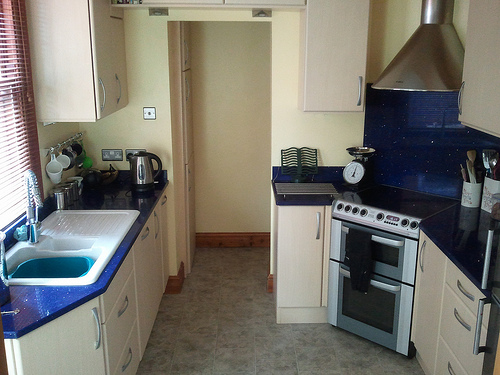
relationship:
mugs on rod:
[436, 179, 490, 224] [29, 123, 121, 180]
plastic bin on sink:
[7, 254, 94, 278] [2, 205, 144, 292]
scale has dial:
[337, 140, 379, 193] [342, 141, 379, 161]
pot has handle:
[128, 152, 169, 195] [142, 150, 165, 182]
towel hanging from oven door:
[346, 222, 373, 297] [333, 220, 409, 283]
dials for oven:
[335, 202, 418, 237] [334, 210, 396, 342]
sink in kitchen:
[2, 205, 144, 292] [3, 2, 484, 362]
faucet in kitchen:
[21, 167, 43, 234] [3, 2, 484, 362]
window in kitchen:
[1, 8, 50, 267] [3, 2, 484, 362]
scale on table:
[343, 146, 376, 193] [272, 180, 365, 206]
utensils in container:
[457, 150, 482, 180] [475, 175, 498, 216]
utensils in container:
[478, 147, 498, 180] [459, 180, 481, 208]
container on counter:
[475, 175, 498, 216] [420, 201, 498, 297]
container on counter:
[459, 180, 481, 208] [420, 201, 498, 297]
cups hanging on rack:
[41, 136, 86, 188] [42, 126, 87, 153]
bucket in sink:
[11, 250, 108, 283] [0, 190, 141, 291]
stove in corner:
[337, 185, 446, 220] [260, 148, 485, 238]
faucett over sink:
[24, 169, 43, 243] [4, 209, 141, 285]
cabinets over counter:
[24, 1, 131, 128] [0, 171, 170, 341]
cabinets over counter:
[300, 1, 372, 113] [271, 165, 491, 293]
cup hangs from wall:
[57, 141, 73, 171] [34, 120, 95, 192]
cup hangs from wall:
[40, 146, 68, 185] [34, 120, 95, 192]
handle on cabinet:
[82, 302, 108, 351] [75, 246, 171, 371]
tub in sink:
[14, 251, 97, 293] [4, 196, 139, 302]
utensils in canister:
[460, 151, 483, 185] [458, 180, 482, 206]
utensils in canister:
[480, 149, 499, 178] [479, 175, 499, 215]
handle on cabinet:
[314, 208, 320, 239] [276, 203, 324, 307]